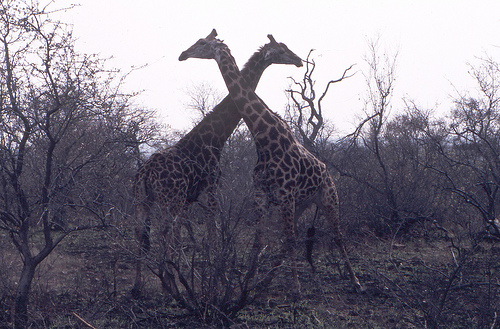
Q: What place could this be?
A: It is a forest.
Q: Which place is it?
A: It is a forest.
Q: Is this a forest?
A: Yes, it is a forest.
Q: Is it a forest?
A: Yes, it is a forest.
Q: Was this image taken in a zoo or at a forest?
A: It was taken at a forest.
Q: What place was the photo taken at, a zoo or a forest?
A: It was taken at a forest.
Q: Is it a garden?
A: No, it is a forest.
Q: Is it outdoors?
A: Yes, it is outdoors.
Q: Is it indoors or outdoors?
A: It is outdoors.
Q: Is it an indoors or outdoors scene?
A: It is outdoors.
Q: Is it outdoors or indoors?
A: It is outdoors.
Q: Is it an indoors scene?
A: No, it is outdoors.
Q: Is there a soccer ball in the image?
A: No, there are no soccer balls.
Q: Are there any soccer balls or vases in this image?
A: No, there are no soccer balls or vases.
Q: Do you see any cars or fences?
A: No, there are no fences or cars.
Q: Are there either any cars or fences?
A: No, there are no fences or cars.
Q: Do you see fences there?
A: No, there are no fences.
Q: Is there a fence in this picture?
A: No, there are no fences.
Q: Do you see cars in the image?
A: No, there are no cars.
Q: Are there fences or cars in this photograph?
A: No, there are no cars or fences.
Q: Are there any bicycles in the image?
A: No, there are no bicycles.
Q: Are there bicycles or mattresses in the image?
A: No, there are no bicycles or mattresses.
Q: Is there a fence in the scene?
A: No, there are no fences.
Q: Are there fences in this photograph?
A: No, there are no fences.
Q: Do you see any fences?
A: No, there are no fences.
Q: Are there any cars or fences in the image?
A: No, there are no fences or cars.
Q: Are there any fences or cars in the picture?
A: No, there are no fences or cars.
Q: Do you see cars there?
A: No, there are no cars.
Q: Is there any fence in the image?
A: No, there are no fences.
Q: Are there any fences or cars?
A: No, there are no fences or cars.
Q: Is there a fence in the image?
A: No, there are no fences.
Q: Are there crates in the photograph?
A: No, there are no crates.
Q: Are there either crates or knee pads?
A: No, there are no crates or knee pads.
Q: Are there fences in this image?
A: No, there are no fences.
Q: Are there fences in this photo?
A: No, there are no fences.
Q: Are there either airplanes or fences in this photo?
A: No, there are no fences or airplanes.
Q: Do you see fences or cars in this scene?
A: No, there are no fences or cars.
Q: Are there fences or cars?
A: No, there are no fences or cars.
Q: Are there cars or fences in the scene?
A: No, there are no fences or cars.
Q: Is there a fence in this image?
A: No, there are no fences.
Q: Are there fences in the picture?
A: No, there are no fences.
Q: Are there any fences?
A: No, there are no fences.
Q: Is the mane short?
A: Yes, the mane is short.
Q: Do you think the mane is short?
A: Yes, the mane is short.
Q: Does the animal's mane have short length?
A: Yes, the mane is short.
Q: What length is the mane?
A: The mane is short.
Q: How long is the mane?
A: The mane is short.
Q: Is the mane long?
A: No, the mane is short.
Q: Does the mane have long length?
A: No, the mane is short.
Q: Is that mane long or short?
A: The mane is short.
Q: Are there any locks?
A: No, there are no locks.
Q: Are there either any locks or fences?
A: No, there are no locks or fences.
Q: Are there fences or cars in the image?
A: No, there are no fences or cars.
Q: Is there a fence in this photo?
A: No, there are no fences.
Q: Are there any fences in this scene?
A: No, there are no fences.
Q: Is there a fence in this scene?
A: No, there are no fences.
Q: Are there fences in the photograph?
A: No, there are no fences.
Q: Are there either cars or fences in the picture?
A: No, there are no fences or cars.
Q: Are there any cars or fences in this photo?
A: No, there are no fences or cars.